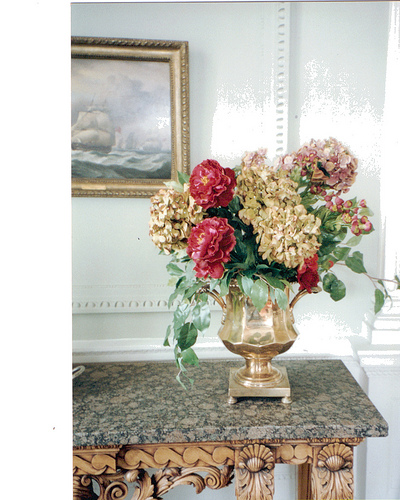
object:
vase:
[194, 275, 323, 405]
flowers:
[148, 188, 206, 257]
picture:
[72, 57, 172, 180]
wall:
[72, 2, 399, 361]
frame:
[72, 35, 192, 199]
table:
[70, 358, 389, 499]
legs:
[299, 437, 355, 499]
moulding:
[72, 1, 292, 316]